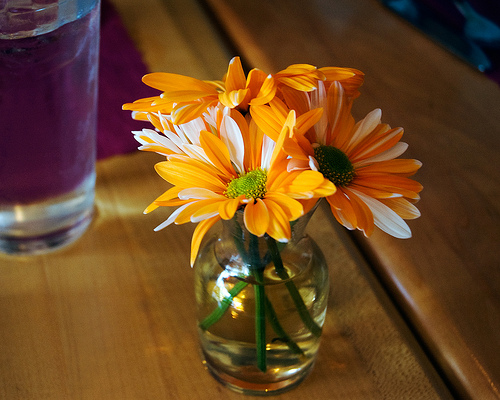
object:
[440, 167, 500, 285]
ground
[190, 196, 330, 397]
vase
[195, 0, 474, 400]
hole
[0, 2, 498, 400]
table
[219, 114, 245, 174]
petal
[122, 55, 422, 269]
flowers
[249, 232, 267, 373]
stem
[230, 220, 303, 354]
stem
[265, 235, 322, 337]
stem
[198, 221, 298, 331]
stem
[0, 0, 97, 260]
glass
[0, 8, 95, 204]
liquid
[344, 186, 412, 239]
petal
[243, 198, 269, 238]
petal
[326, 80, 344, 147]
petal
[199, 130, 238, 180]
petal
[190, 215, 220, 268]
petal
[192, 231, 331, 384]
water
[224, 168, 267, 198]
middle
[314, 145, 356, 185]
middle